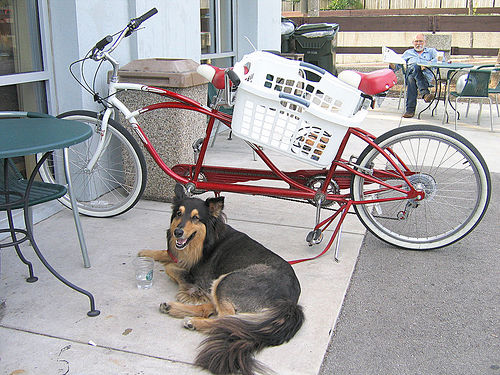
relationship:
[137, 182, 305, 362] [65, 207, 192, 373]
collie on ground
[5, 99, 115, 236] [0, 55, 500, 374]
table on ground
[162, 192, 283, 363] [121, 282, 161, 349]
collie on ground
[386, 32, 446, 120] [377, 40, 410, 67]
man reading newspaper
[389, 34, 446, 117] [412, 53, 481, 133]
man at table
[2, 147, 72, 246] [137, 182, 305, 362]
chair by collie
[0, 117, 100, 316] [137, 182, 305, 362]
table by collie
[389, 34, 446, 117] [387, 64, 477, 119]
man sitting at table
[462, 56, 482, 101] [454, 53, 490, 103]
back of chair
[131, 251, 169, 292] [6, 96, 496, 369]
cup on ground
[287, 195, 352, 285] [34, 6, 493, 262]
leash on bicycle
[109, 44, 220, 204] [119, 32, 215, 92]
trashcan has lid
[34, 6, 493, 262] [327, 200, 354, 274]
bicycle has kickstand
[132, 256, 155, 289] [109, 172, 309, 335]
cup in front of dog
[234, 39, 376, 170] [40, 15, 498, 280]
basket on bike.